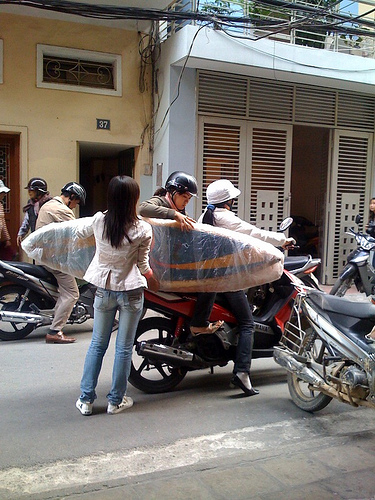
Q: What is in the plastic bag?
A: A surfboard.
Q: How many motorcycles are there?
A: Four.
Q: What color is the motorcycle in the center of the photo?
A: Red.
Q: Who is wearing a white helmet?
A: The driver of the red motorcycle.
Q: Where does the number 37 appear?
A: Above the door of the yellow building.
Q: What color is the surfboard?
A: Blue and yellow.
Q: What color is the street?
A: Grey.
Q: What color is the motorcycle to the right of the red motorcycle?
A: Silver.